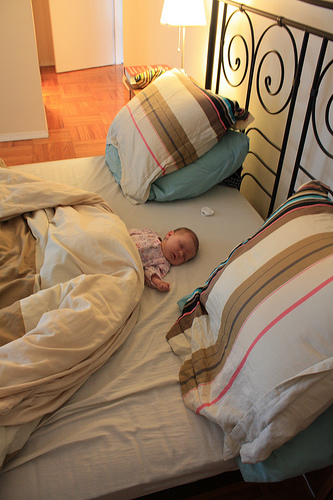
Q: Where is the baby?
A: On the bed.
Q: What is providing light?
A: A lamp.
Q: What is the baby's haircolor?
A: Brown.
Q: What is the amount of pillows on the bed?
A: 4.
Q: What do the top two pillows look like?
A: They are striped.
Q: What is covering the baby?
A: A blanket.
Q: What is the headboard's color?
A: Black.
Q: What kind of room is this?
A: Bedroom.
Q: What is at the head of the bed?
A: Metal headboard.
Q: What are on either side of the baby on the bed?
A: Pillows.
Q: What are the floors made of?
A: Hardwood floors.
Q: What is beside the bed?
A: Lamp.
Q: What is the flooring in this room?
A: Wood.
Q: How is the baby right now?
A: Sleeping.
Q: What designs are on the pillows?
A: Stripes.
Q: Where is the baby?
A: In the middle of the bed.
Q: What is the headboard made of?
A: Metal.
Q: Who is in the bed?
A: A baby.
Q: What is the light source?
A: A lamp.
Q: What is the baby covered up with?
A: Blankets.